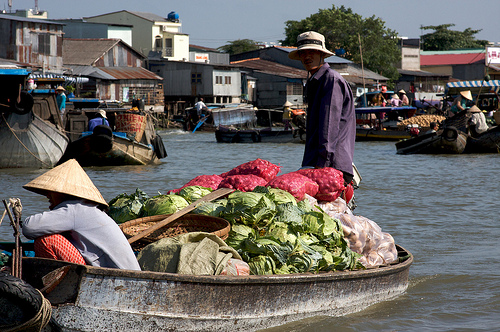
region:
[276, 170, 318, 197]
the bag is red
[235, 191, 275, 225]
the cabbage is green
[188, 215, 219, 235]
the basket is a woven design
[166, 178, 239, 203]
the ore is wooden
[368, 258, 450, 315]
the boat is in the water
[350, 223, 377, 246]
the bag is white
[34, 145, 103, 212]
the hat is cream color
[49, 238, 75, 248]
the pants are orange and white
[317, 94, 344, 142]
the shirt is dark blue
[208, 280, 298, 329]
the boat has calcium build up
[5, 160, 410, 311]
boat filled with produce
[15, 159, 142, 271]
man in a triangle shaped hat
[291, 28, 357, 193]
man standing on a boat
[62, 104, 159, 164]
boat in the water with a large basket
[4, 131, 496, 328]
body of water used for boats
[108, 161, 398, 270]
produce on top of a boat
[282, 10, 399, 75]
large green tree behind the buildings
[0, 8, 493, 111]
buildings behind the body of water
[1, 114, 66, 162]
front view of a white boat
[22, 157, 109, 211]
triangle straw hat on the man's head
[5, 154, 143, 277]
Woman crouched down in a boat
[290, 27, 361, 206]
Man standing in boat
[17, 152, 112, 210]
Woman wearing straw hat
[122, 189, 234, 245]
Paddle resting on basket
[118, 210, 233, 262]
Basket sitting in boat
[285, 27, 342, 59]
Man is wearing a hat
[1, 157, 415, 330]
Boat is in the water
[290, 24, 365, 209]
Man is steering the boat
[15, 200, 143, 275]
Woman is wearing light blue shirt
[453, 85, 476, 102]
Woman wearing straw hat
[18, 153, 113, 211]
sedge hat, asian conical hat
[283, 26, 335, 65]
australian 'outback' not conical hat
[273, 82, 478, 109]
several conical hats in distance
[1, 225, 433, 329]
old, somewhat tattered, rowboat good for transporting produce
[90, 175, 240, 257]
straight oar, one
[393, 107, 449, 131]
big pile of potatoes waiting for packing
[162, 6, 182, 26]
person mending roof onshore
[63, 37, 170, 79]
rusty aluminium roofs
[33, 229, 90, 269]
red+white patterned pants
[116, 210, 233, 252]
the top of a woven basket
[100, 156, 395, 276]
pile of vegetables in the boat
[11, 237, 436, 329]
gray boat in the water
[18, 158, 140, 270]
man wearing a pointed hat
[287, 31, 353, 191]
man wearing a white hat in the boat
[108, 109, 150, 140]
basket with red letters on it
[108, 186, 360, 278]
pile of lettuce in the boat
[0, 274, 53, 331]
tire with a rope on it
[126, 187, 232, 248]
wooden oar to paddle the boat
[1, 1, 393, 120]
buildings next to the water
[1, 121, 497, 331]
body of water full of boats